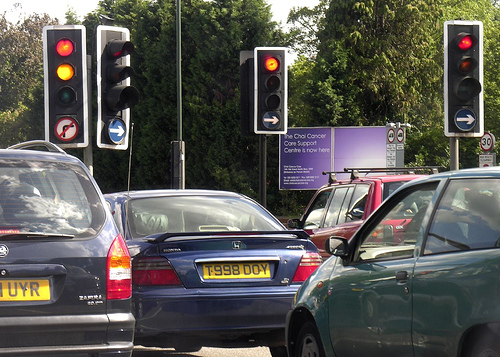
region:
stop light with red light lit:
[242, 42, 294, 144]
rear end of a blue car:
[112, 185, 327, 346]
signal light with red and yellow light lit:
[35, 17, 99, 159]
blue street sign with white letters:
[276, 128, 411, 193]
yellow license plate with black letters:
[200, 260, 280, 285]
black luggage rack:
[310, 159, 440, 187]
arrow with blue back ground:
[104, 115, 141, 150]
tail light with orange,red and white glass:
[100, 237, 141, 309]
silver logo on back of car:
[277, 234, 318, 254]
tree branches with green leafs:
[287, 7, 332, 57]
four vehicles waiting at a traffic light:
[2, 22, 494, 354]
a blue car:
[100, 190, 322, 337]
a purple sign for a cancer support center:
[278, 125, 407, 189]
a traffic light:
[443, 18, 483, 137]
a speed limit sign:
[478, 130, 498, 166]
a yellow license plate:
[193, 259, 278, 278]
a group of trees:
[292, 1, 442, 125]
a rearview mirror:
[324, 235, 349, 265]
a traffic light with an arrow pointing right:
[254, 45, 288, 132]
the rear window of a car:
[120, 193, 298, 238]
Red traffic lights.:
[37, 3, 487, 62]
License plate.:
[192, 254, 286, 287]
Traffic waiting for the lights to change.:
[12, 137, 481, 355]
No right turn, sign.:
[42, 111, 84, 148]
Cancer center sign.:
[286, 115, 414, 181]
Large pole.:
[165, 62, 200, 185]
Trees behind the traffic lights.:
[121, 49, 254, 163]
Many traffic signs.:
[382, 122, 408, 172]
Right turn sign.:
[108, 115, 137, 145]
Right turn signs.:
[254, 111, 483, 135]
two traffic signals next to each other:
[42, 20, 141, 155]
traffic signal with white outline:
[235, 35, 304, 140]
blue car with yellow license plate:
[96, 182, 347, 339]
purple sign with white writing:
[276, 113, 399, 195]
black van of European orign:
[0, 141, 146, 353]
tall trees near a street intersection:
[106, 0, 280, 195]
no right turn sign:
[48, 110, 88, 147]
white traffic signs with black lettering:
[383, 122, 411, 192]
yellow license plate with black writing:
[196, 256, 273, 281]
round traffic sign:
[103, 117, 134, 146]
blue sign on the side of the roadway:
[276, 122, 408, 194]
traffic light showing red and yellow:
[38, 26, 88, 151]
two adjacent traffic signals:
[38, 17, 136, 152]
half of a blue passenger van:
[2, 134, 143, 355]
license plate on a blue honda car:
[190, 257, 275, 283]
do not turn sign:
[53, 115, 83, 143]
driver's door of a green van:
[326, 175, 415, 355]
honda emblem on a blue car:
[229, 237, 241, 251]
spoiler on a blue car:
[142, 224, 310, 241]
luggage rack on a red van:
[321, 161, 442, 178]